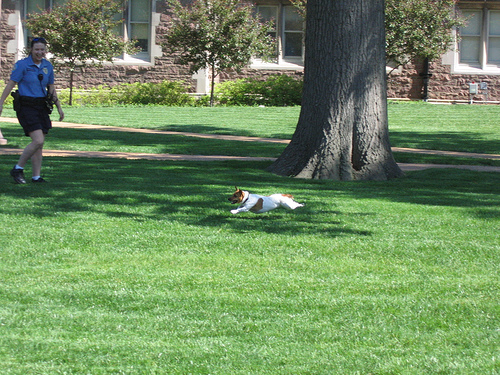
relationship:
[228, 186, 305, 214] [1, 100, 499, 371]
dog laying in grass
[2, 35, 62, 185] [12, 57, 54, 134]
woman wearing uniform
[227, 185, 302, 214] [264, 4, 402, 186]
dog near tree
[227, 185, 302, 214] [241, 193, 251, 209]
dog wearing collar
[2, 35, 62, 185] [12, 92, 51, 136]
woman wearing shorts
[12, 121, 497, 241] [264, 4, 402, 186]
shadow of tree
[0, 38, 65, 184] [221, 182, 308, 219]
woman smiling at dog